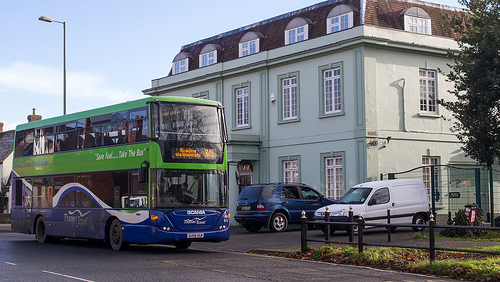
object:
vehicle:
[234, 181, 331, 233]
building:
[141, 0, 499, 226]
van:
[312, 178, 431, 238]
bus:
[12, 96, 234, 254]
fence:
[299, 208, 500, 264]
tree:
[433, 1, 499, 174]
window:
[367, 186, 393, 207]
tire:
[269, 212, 289, 232]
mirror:
[137, 166, 150, 184]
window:
[150, 101, 224, 143]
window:
[154, 167, 229, 207]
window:
[123, 106, 148, 146]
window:
[13, 177, 24, 207]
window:
[319, 65, 344, 116]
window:
[279, 73, 299, 122]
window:
[232, 85, 250, 130]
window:
[417, 66, 438, 115]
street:
[1, 232, 457, 281]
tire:
[108, 218, 128, 252]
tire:
[33, 214, 48, 246]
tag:
[186, 232, 205, 239]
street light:
[36, 16, 55, 26]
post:
[59, 20, 68, 115]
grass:
[292, 243, 500, 279]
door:
[447, 167, 479, 226]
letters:
[140, 151, 144, 157]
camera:
[382, 136, 393, 146]